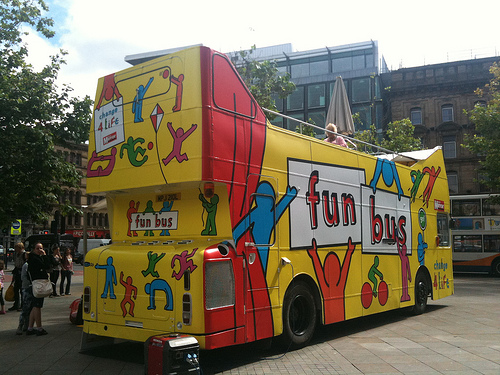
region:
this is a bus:
[110, 94, 448, 290]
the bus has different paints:
[219, 164, 356, 243]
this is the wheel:
[286, 285, 328, 348]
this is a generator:
[144, 331, 188, 373]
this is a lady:
[26, 242, 52, 347]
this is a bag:
[21, 274, 55, 296]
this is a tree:
[12, 87, 54, 170]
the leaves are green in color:
[18, 103, 42, 144]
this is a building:
[408, 72, 450, 147]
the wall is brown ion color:
[423, 97, 443, 122]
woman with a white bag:
[23, 241, 53, 337]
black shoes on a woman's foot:
[23, 326, 50, 336]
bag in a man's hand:
[4, 276, 20, 303]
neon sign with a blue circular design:
[9, 219, 22, 235]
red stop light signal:
[42, 228, 49, 234]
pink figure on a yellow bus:
[168, 246, 199, 281]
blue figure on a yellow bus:
[141, 276, 172, 311]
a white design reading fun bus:
[128, 210, 178, 227]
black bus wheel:
[282, 277, 320, 349]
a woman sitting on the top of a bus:
[321, 121, 346, 146]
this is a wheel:
[287, 290, 309, 343]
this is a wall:
[400, 64, 492, 116]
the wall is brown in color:
[423, 95, 433, 138]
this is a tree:
[462, 90, 498, 175]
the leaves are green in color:
[476, 114, 499, 127]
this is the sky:
[53, 10, 128, 80]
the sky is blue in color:
[51, 5, 61, 20]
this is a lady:
[30, 236, 57, 305]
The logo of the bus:
[301, 168, 411, 244]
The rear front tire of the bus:
[282, 283, 319, 340]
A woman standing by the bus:
[28, 243, 48, 334]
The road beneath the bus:
[397, 311, 480, 369]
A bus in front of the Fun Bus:
[455, 195, 497, 272]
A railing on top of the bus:
[271, 109, 416, 161]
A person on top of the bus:
[323, 121, 343, 143]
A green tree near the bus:
[5, 66, 63, 219]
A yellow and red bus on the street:
[88, 72, 455, 325]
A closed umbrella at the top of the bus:
[326, 72, 353, 132]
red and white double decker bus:
[103, 57, 461, 334]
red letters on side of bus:
[292, 166, 399, 239]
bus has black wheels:
[281, 285, 328, 330]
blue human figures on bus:
[226, 174, 348, 284]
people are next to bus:
[7, 251, 84, 331]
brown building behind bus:
[35, 146, 117, 256]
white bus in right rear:
[436, 191, 499, 287]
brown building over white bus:
[395, 91, 492, 176]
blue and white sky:
[40, 16, 110, 70]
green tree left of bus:
[0, 22, 73, 287]